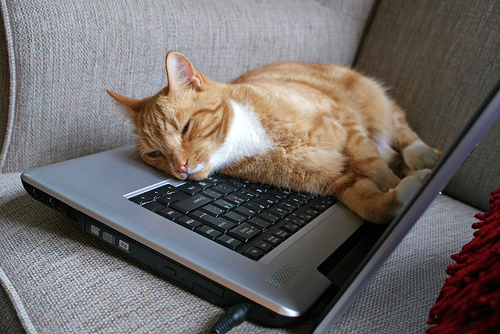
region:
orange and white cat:
[106, 49, 444, 228]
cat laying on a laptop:
[19, 49, 496, 332]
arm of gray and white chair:
[1, 2, 374, 170]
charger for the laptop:
[203, 297, 252, 332]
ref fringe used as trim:
[428, 188, 498, 333]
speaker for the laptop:
[263, 255, 308, 288]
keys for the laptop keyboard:
[127, 172, 335, 259]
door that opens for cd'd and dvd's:
[113, 235, 227, 304]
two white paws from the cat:
[396, 138, 444, 222]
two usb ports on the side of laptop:
[23, 185, 65, 212]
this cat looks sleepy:
[101, 46, 443, 228]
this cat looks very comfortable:
[101, 47, 445, 226]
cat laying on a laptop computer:
[21, 42, 499, 325]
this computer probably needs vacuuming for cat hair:
[18, 58, 496, 325]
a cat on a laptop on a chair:
[6, 48, 497, 329]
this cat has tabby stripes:
[99, 40, 446, 225]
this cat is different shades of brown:
[100, 45, 451, 228]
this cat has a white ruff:
[99, 44, 444, 226]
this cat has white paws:
[100, 45, 448, 227]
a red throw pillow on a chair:
[426, 182, 499, 330]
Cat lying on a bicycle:
[19, 46, 495, 327]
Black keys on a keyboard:
[130, 168, 337, 260]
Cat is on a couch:
[3, 1, 497, 326]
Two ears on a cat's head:
[105, 49, 204, 115]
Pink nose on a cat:
[170, 158, 190, 177]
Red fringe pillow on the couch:
[424, 185, 496, 331]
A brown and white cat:
[105, 49, 446, 226]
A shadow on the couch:
[1, 190, 147, 267]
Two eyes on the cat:
[142, 116, 194, 161]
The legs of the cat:
[339, 116, 443, 227]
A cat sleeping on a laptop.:
[149, 75, 401, 200]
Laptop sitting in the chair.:
[23, 123, 468, 295]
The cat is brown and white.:
[239, 55, 376, 180]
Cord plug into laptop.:
[208, 295, 255, 332]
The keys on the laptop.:
[177, 175, 277, 247]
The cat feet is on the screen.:
[346, 145, 442, 218]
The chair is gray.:
[19, 11, 376, 107]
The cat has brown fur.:
[267, 71, 379, 130]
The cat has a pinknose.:
[167, 163, 194, 174]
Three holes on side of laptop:
[29, 183, 60, 209]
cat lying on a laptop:
[131, 59, 431, 219]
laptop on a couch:
[20, 60, 490, 285]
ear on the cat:
[158, 41, 203, 91]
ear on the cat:
[102, 74, 139, 123]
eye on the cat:
[178, 113, 210, 148]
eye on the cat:
[135, 138, 165, 168]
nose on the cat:
[167, 157, 197, 183]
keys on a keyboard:
[202, 184, 284, 241]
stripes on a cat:
[339, 105, 372, 164]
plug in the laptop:
[210, 301, 240, 332]